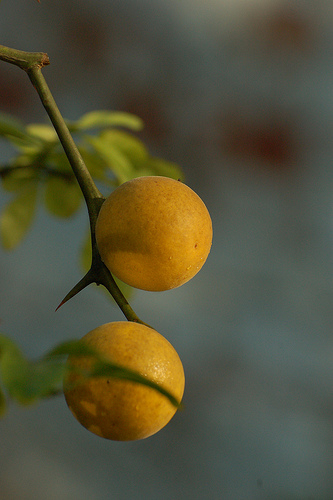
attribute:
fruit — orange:
[94, 176, 214, 293]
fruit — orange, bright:
[61, 320, 186, 443]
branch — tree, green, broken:
[1, 45, 160, 333]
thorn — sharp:
[56, 272, 96, 313]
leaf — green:
[68, 110, 144, 131]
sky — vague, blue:
[1, 2, 331, 500]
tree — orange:
[1, 44, 188, 415]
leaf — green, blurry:
[84, 137, 135, 182]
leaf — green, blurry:
[42, 173, 81, 220]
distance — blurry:
[2, 1, 332, 498]